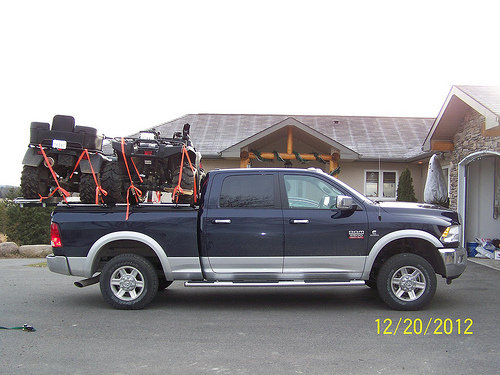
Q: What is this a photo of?
A: A truck.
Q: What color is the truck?
A: Navy blue.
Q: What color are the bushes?
A: Green.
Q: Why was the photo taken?
A: To show a truck.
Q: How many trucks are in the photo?
A: One.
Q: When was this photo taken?
A: In the daytime.